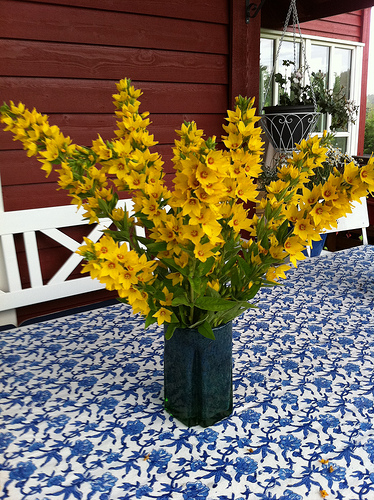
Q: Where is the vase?
A: On a table.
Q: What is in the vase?
A: Flowers.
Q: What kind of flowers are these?
A: Yellow flowers.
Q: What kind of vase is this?
A: Blue vase.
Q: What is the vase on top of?
A: Blue and white tablecloth.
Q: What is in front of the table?
A: White chair.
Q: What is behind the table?
A: Red house.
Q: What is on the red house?
A: Window.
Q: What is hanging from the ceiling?
A: Flower pot.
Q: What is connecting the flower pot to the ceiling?
A: Chain.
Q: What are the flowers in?
A: A vase.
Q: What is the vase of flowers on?
A: A table.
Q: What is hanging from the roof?
A: A planter.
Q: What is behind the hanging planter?
A: A window.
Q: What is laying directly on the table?
A: A blue and white tablecloth.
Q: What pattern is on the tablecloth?
A: Floral.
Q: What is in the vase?
A: Yellow flowers.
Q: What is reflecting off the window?
A: Trees and the sky.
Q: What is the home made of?
A: Wood.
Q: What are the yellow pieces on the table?
A: Flower petals.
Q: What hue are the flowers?
A: Yellow.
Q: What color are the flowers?
A: Yellow.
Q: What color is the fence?
A: White.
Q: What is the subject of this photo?
A: Flowers.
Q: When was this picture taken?
A: Daytime.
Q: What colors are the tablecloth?
A: Blue and white.